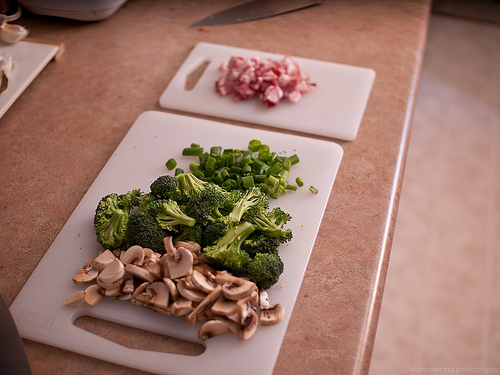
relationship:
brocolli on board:
[119, 163, 246, 240] [156, 129, 185, 152]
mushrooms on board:
[144, 266, 214, 325] [156, 129, 185, 152]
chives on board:
[211, 148, 284, 180] [156, 129, 185, 152]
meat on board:
[229, 64, 300, 102] [156, 129, 185, 152]